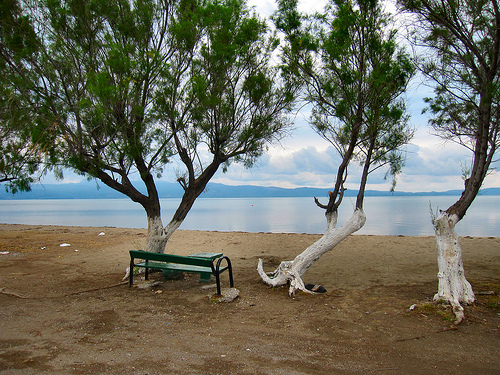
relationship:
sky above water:
[0, 1, 499, 192] [1, 198, 497, 242]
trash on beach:
[60, 243, 70, 246] [1, 222, 499, 374]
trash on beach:
[98, 231, 104, 235] [1, 222, 499, 374]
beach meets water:
[1, 222, 499, 374] [1, 198, 497, 242]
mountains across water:
[2, 178, 499, 195] [1, 198, 497, 242]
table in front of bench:
[188, 252, 223, 280] [117, 247, 238, 295]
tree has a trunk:
[395, 0, 499, 322] [426, 92, 496, 328]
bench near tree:
[117, 247, 238, 295] [258, 0, 419, 298]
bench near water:
[117, 247, 238, 295] [1, 198, 497, 242]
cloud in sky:
[194, 108, 498, 187] [0, 1, 499, 192]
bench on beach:
[117, 247, 238, 295] [1, 222, 499, 374]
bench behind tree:
[117, 247, 238, 295] [258, 0, 419, 298]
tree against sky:
[258, 0, 419, 298] [0, 1, 499, 192]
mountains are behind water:
[2, 178, 499, 195] [1, 198, 497, 242]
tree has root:
[258, 0, 419, 298] [257, 256, 286, 288]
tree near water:
[395, 0, 499, 322] [1, 198, 497, 242]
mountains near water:
[2, 178, 499, 195] [1, 198, 497, 242]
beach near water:
[1, 222, 499, 374] [1, 198, 497, 242]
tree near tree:
[395, 0, 499, 322] [258, 0, 419, 298]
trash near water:
[60, 243, 70, 246] [1, 198, 497, 242]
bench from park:
[117, 247, 238, 295] [18, 14, 491, 366]